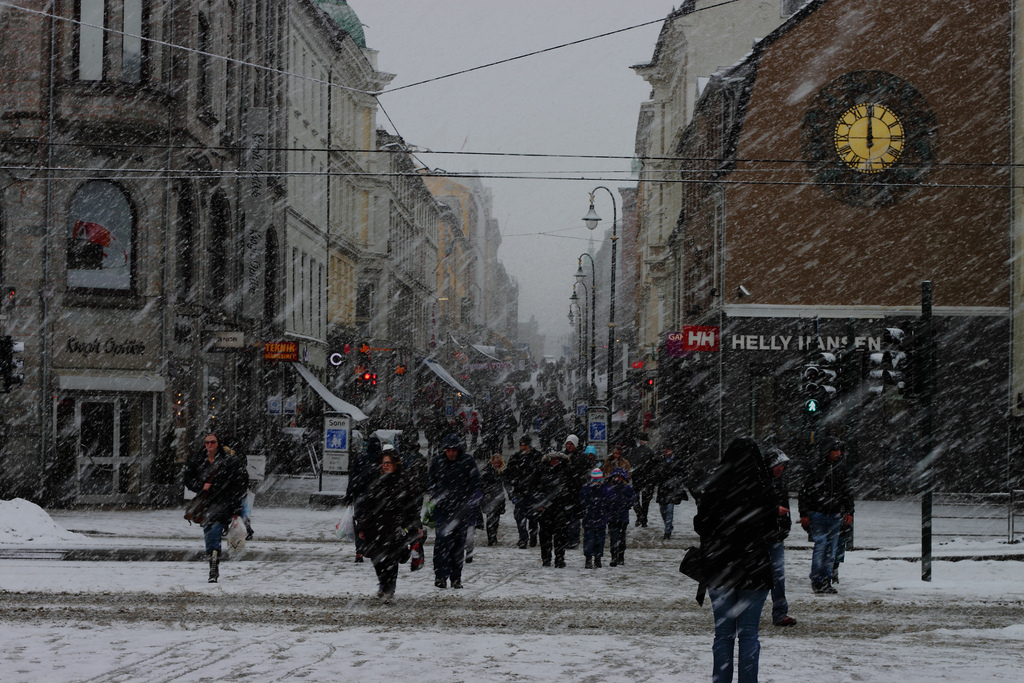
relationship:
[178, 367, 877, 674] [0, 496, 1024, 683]
people in snow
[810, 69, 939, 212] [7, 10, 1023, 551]
clock on building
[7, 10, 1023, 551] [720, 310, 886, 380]
building has sign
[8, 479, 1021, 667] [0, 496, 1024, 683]
snow in snow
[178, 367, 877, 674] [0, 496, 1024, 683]
people on snow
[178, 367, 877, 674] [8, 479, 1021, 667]
people in snow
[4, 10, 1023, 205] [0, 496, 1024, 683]
wire on snow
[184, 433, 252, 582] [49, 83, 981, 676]
people on a snowy day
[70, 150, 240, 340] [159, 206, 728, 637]
window in snow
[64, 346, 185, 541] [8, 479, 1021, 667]
doors in snow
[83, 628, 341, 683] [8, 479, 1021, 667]
tracks in snow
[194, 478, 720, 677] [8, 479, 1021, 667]
tracks in snow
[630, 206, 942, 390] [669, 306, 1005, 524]
roofing front of shop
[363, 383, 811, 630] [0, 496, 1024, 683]
pedestrians on snow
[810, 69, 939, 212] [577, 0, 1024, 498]
clock on building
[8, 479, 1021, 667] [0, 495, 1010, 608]
snow on drift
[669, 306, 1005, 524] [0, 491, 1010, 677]
shop in street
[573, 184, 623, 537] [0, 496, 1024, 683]
lamp post along snow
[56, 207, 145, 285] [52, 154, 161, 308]
decorations are in a window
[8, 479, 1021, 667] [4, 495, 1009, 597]
snow on a drift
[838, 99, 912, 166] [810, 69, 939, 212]
numerals are on a clock